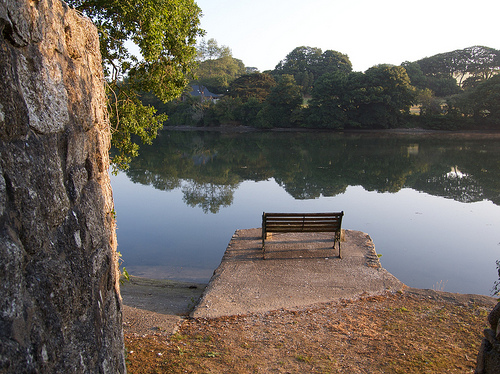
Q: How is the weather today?
A: It is clear.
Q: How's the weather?
A: It is clear.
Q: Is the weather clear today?
A: Yes, it is clear.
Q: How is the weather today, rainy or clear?
A: It is clear.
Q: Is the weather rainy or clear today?
A: It is clear.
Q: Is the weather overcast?
A: No, it is clear.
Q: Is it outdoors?
A: Yes, it is outdoors.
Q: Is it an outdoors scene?
A: Yes, it is outdoors.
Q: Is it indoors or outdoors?
A: It is outdoors.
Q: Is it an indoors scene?
A: No, it is outdoors.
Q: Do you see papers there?
A: No, there are no papers.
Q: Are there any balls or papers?
A: No, there are no papers or balls.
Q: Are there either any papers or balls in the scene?
A: No, there are no papers or balls.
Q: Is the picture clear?
A: Yes, the picture is clear.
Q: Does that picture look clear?
A: Yes, the picture is clear.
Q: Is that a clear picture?
A: Yes, that is a clear picture.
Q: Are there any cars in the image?
A: No, there are no cars.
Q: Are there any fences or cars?
A: No, there are no cars or fences.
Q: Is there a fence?
A: No, there are no fences.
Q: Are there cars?
A: No, there are no cars.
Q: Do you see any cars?
A: No, there are no cars.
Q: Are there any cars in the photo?
A: No, there are no cars.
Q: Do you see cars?
A: No, there are no cars.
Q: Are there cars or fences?
A: No, there are no cars or fences.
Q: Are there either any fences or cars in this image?
A: No, there are no cars or fences.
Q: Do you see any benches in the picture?
A: Yes, there is a bench.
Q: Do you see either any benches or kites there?
A: Yes, there is a bench.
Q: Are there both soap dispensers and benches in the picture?
A: No, there is a bench but no soap dispensers.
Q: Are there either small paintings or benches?
A: Yes, there is a small bench.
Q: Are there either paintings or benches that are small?
A: Yes, the bench is small.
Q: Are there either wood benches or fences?
A: Yes, there is a wood bench.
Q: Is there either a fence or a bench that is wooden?
A: Yes, the bench is wooden.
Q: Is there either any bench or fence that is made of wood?
A: Yes, the bench is made of wood.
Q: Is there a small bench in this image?
A: Yes, there is a small bench.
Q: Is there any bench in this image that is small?
A: Yes, there is a bench that is small.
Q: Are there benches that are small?
A: Yes, there is a bench that is small.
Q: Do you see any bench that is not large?
A: Yes, there is a small bench.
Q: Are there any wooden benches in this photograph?
A: Yes, there is a wood bench.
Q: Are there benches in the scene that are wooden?
A: Yes, there is a bench that is wooden.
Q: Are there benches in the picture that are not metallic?
A: Yes, there is a wooden bench.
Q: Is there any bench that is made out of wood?
A: Yes, there is a bench that is made of wood.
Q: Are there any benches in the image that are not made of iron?
A: Yes, there is a bench that is made of wood.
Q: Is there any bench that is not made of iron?
A: Yes, there is a bench that is made of wood.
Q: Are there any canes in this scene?
A: No, there are no canes.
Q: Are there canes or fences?
A: No, there are no canes or fences.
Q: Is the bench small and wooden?
A: Yes, the bench is small and wooden.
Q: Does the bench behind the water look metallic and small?
A: No, the bench is small but wooden.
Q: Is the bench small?
A: Yes, the bench is small.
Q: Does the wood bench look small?
A: Yes, the bench is small.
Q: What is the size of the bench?
A: The bench is small.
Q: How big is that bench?
A: The bench is small.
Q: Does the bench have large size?
A: No, the bench is small.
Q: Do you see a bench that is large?
A: No, there is a bench but it is small.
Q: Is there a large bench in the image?
A: No, there is a bench but it is small.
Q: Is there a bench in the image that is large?
A: No, there is a bench but it is small.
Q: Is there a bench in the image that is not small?
A: No, there is a bench but it is small.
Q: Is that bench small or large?
A: The bench is small.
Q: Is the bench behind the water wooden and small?
A: Yes, the bench is wooden and small.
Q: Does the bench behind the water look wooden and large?
A: No, the bench is wooden but small.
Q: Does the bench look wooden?
A: Yes, the bench is wooden.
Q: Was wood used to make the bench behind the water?
A: Yes, the bench is made of wood.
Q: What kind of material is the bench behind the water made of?
A: The bench is made of wood.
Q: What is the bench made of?
A: The bench is made of wood.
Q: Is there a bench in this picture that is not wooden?
A: No, there is a bench but it is wooden.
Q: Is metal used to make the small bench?
A: No, the bench is made of wood.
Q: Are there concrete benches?
A: No, there is a bench but it is made of wood.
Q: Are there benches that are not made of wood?
A: No, there is a bench but it is made of wood.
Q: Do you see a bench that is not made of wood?
A: No, there is a bench but it is made of wood.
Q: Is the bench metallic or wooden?
A: The bench is wooden.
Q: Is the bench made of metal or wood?
A: The bench is made of wood.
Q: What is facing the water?
A: The bench is facing the water.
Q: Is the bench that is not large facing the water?
A: Yes, the bench is facing the water.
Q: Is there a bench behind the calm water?
A: Yes, there is a bench behind the water.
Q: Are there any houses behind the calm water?
A: No, there is a bench behind the water.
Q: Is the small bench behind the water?
A: Yes, the bench is behind the water.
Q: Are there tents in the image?
A: No, there are no tents.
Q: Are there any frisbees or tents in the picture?
A: No, there are no tents or frisbees.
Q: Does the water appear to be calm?
A: Yes, the water is calm.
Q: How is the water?
A: The water is calm.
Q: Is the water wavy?
A: No, the water is calm.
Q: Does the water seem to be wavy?
A: No, the water is calm.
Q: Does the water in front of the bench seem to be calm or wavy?
A: The water is calm.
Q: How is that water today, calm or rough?
A: The water is calm.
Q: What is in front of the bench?
A: The water is in front of the bench.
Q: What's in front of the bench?
A: The water is in front of the bench.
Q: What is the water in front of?
A: The water is in front of the bench.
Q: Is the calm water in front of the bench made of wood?
A: Yes, the water is in front of the bench.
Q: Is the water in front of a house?
A: No, the water is in front of the bench.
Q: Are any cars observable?
A: No, there are no cars.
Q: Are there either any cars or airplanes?
A: No, there are no cars or airplanes.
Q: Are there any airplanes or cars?
A: No, there are no cars or airplanes.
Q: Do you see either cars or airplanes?
A: No, there are no cars or airplanes.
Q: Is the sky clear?
A: Yes, the sky is clear.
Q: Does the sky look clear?
A: Yes, the sky is clear.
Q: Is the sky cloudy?
A: No, the sky is clear.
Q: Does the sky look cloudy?
A: No, the sky is clear.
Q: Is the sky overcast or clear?
A: The sky is clear.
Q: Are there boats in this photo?
A: No, there are no boats.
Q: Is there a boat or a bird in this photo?
A: No, there are no boats or birds.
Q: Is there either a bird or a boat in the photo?
A: No, there are no boats or birds.